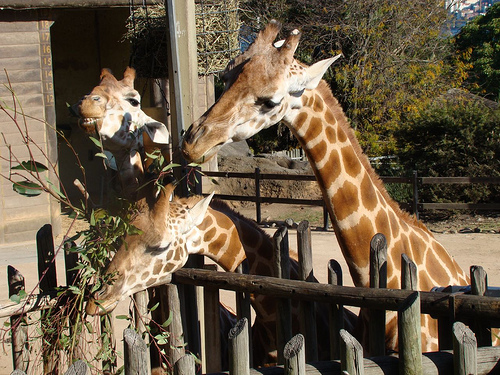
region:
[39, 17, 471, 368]
the giraffes are eating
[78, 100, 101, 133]
the giraffe is showing his teeth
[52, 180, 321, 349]
the giraffe is leaning over a fence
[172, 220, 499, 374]
the fence is wooden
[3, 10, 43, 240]
the building has siding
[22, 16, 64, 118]
the building has numbers on the door frame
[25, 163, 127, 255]
the leaves are green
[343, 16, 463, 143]
the trees leaves are turning yellow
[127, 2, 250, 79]
hay for feeding in the background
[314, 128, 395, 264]
the giraffes spots are brown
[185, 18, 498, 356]
A tall giraffe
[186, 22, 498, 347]
the giraffe is brown and spotted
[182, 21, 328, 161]
The face of the tall giraffe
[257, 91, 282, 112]
The eye of the giraffe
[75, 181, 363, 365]
A short giraffe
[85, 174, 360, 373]
The giraffe is leaning over the fence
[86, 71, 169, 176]
A giraffe beside a building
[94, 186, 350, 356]
the giraffe is spotted and brown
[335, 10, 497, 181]
brown and green trees behind the giraffes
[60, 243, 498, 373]
a small wooden fence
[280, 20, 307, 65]
a horn of a giraffe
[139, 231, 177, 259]
an eye of a giraffe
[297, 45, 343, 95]
an ear of a giraffe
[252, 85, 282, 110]
an eye of a giraffe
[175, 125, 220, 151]
a nose of a giraffe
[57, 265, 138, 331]
a giraffe eat leaves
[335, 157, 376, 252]
spots on a giraffe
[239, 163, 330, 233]
a metal gate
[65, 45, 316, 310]
three giraffe heads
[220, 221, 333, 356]
a wood pole fence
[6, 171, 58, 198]
small green leaf on tree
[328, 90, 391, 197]
small brown comb on giraffe's back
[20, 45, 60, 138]
dirt on wooden door side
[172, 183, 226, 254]
white ears on small giraffe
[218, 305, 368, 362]
small gray stumps on ground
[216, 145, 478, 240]
black posts in corral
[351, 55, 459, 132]
yellow trees in the distance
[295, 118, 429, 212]
brown and tan design on giraffe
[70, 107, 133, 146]
white teeth in giraffe's mouth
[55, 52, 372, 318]
giraffe eating grass in pen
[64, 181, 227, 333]
A giraffe munching on some leaves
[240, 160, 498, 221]
A wood fence in the background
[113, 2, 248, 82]
Hay up high in a cage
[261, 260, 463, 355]
A cut wooden pole fence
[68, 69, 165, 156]
A grinning giraffe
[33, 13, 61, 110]
Numbers running down a wall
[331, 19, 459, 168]
Yellow leaves on a tree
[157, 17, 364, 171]
A giraffe looking at the back of another giraffe's head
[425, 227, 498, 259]
Rocks lining the giraffe pen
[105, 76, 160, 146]
Light shining on a giraffe's face